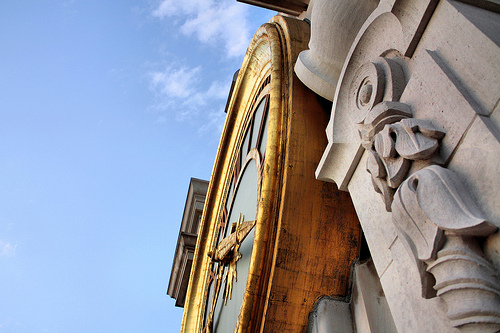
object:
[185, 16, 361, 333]
clock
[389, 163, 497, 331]
design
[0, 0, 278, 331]
sky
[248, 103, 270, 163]
number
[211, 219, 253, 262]
clock hand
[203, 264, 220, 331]
clock hand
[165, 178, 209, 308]
roof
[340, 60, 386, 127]
design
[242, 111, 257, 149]
gold line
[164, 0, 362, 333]
building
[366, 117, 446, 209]
wave design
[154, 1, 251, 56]
cloud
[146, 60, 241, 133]
cloud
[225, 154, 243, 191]
number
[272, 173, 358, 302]
side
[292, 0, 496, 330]
building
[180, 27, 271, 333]
face